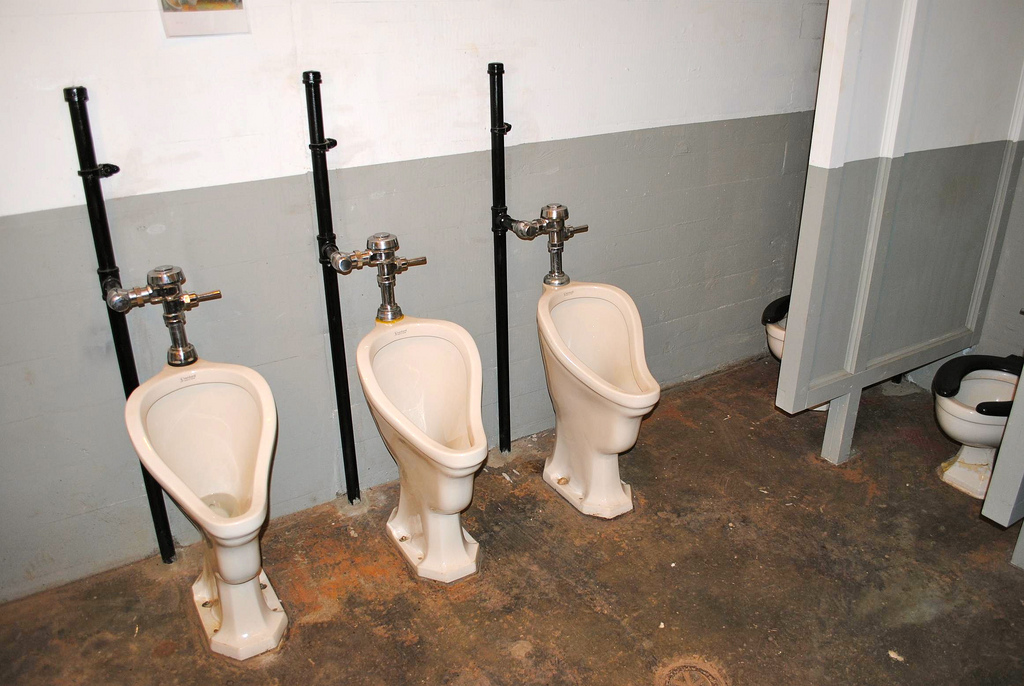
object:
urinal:
[123, 360, 288, 662]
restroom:
[0, 0, 1024, 686]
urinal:
[356, 317, 488, 584]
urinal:
[537, 281, 660, 518]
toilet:
[931, 354, 1024, 500]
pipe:
[302, 70, 360, 505]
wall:
[0, 0, 1024, 603]